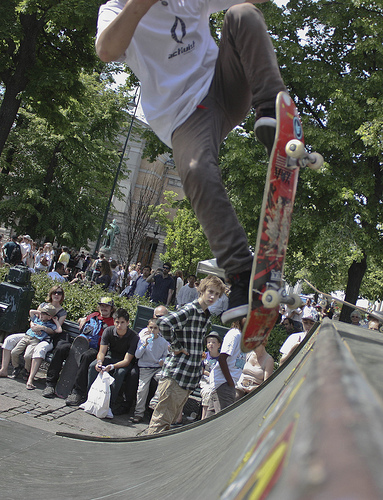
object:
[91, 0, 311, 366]
guy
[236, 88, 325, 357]
skateboard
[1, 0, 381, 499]
air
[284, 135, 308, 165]
wheel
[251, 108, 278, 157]
shoe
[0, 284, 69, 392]
spectator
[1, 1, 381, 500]
skateboarding show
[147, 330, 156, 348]
bottled water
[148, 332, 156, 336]
mouth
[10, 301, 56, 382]
kid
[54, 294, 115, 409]
guy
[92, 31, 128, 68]
elbow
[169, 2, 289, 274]
pants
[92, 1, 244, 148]
shirt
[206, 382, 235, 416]
pants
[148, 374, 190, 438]
pants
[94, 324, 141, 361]
shirt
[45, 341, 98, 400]
pants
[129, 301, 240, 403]
bench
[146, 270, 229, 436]
boy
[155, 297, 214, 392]
shirt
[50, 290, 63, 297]
sunglasses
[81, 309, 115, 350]
shirt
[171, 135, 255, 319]
legs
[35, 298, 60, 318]
hat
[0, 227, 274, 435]
crowd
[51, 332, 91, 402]
skateboard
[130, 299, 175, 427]
man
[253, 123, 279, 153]
sole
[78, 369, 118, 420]
bag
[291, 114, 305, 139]
sticker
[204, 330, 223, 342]
hat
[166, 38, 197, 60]
text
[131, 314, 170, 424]
boy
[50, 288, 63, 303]
face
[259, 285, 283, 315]
wheel